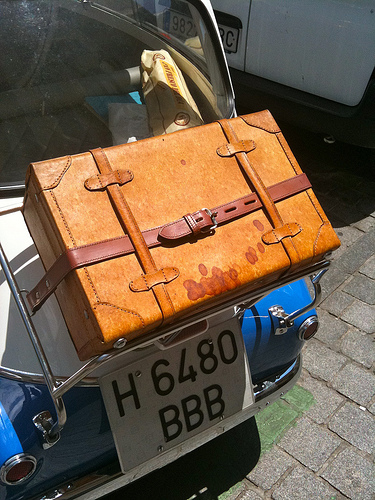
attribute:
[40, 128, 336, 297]
suitcase — vintage , leather  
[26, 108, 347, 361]
tan suitcase — large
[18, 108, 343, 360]
suitcase — tan , leather , strapped 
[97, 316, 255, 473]
license plate — white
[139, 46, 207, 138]
bag — brown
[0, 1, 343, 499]
blue car — vintage 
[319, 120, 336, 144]
ground — black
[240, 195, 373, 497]
pavement — Bricked 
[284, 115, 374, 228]
shadow — of car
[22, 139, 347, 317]
suitcase — strapped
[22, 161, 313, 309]
strap — brown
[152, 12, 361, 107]
car — blue 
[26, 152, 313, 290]
leather strap — brown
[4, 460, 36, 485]
light — round 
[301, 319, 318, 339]
light — round 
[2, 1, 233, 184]
glass — dirty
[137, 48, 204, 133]
bread — fresh